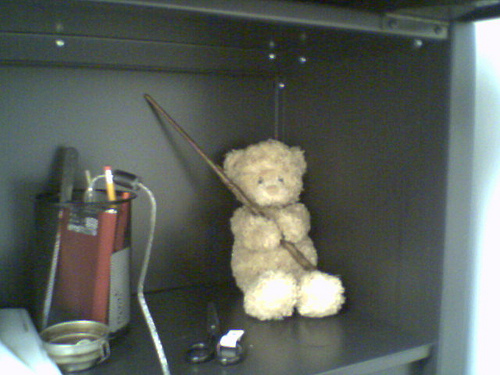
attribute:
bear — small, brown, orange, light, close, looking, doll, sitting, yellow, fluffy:
[213, 136, 349, 324]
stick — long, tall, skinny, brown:
[132, 98, 224, 184]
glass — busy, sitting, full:
[54, 192, 150, 338]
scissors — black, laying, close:
[198, 308, 257, 374]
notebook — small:
[32, 136, 140, 293]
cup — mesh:
[46, 193, 148, 339]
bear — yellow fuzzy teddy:
[227, 125, 351, 333]